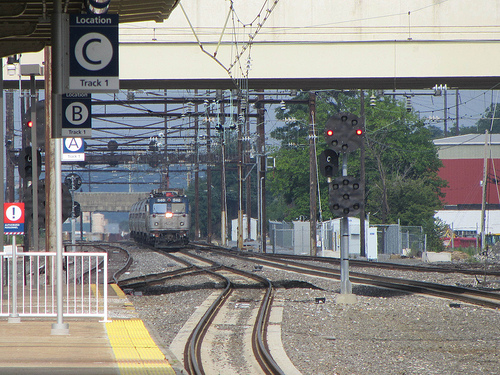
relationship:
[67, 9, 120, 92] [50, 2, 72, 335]
sign on pole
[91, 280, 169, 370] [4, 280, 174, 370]
edge on platform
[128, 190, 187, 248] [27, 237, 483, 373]
train on tracks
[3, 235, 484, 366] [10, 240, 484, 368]
ground in rocks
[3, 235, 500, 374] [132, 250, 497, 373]
ground covered in gravel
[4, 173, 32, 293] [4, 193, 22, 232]
red and blue warning sign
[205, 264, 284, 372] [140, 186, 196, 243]
tracks around train